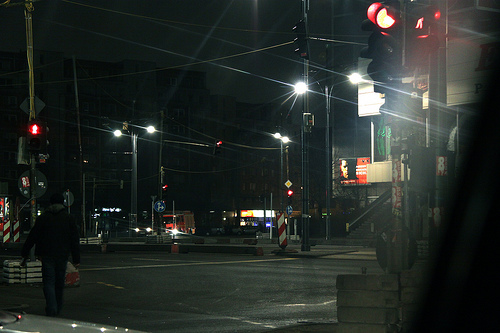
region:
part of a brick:
[354, 298, 385, 325]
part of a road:
[210, 254, 243, 279]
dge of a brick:
[357, 278, 378, 325]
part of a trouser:
[51, 260, 76, 291]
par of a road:
[211, 264, 256, 308]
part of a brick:
[325, 268, 381, 318]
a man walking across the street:
[16, 168, 217, 332]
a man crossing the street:
[9, 118, 261, 331]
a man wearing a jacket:
[7, 141, 137, 331]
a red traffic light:
[349, 1, 456, 221]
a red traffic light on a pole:
[337, 2, 457, 209]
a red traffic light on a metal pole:
[337, 9, 462, 305]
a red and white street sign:
[223, 189, 325, 286]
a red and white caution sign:
[266, 189, 317, 271]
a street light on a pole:
[236, 23, 358, 242]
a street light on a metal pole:
[262, 14, 390, 235]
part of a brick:
[351, 270, 382, 298]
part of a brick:
[348, 288, 376, 314]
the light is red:
[343, 2, 417, 84]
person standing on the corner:
[6, 151, 122, 313]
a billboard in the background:
[316, 147, 378, 195]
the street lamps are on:
[70, 40, 385, 167]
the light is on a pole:
[270, 47, 329, 306]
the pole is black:
[287, 61, 322, 264]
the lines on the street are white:
[92, 245, 294, 287]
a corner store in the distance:
[203, 194, 286, 232]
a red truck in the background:
[139, 194, 211, 242]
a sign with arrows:
[142, 192, 171, 215]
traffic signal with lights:
[356, 2, 443, 94]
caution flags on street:
[267, 208, 294, 255]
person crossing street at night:
[10, 198, 104, 321]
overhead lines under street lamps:
[82, 98, 327, 243]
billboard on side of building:
[328, 121, 394, 252]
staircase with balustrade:
[339, 179, 414, 253]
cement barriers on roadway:
[1, 253, 58, 285]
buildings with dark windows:
[8, 41, 385, 236]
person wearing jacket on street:
[22, 190, 85, 317]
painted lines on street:
[77, 250, 314, 277]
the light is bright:
[270, 69, 332, 131]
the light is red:
[370, 8, 397, 39]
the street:
[215, 284, 284, 308]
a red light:
[362, 5, 402, 30]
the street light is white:
[135, 122, 158, 137]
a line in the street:
[112, 256, 157, 276]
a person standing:
[38, 207, 74, 319]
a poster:
[333, 160, 370, 182]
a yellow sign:
[281, 175, 298, 187]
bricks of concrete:
[341, 278, 380, 322]